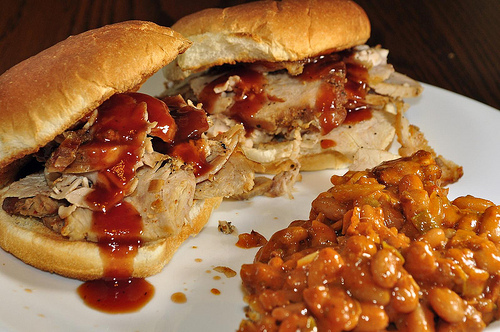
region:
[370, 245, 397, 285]
baked bean piled on white plate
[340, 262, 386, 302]
baked bean piled on white plate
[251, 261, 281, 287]
baked bean piled on white plate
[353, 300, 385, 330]
baked bean piled on white plate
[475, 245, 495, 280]
baked bean piled on white plate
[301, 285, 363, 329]
baked bean piled on white plate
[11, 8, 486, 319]
a white plate of food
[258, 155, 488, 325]
serving of baked beans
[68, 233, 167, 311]
dripping bbq sauce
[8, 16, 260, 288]
bbq beef sandwhich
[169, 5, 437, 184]
bbq pork sandwich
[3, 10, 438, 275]
two sandwiches with toasted buns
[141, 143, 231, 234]
a hunk of meat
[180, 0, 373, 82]
top bun of bun set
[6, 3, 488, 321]
bbq dinner on a white plate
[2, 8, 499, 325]
food on a round white plate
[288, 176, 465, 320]
beans and rice on a plate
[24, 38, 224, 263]
sandwich on a plate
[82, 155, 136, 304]
barbecue sauce on the plate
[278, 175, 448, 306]
beans on a white plate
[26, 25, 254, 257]
half of sandwich on a plate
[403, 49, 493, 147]
white plate on a table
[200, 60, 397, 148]
meat in between the bread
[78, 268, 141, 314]
red sauce on the plate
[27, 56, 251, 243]
sandwich with meat and sauce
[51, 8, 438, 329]
food on a white plate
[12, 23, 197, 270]
this is a sandwich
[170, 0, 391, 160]
this is a sandwich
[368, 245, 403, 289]
this is a grain of bean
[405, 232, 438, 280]
this is a grain of bean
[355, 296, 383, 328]
this is a grain of bean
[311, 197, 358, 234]
this is a grain of bean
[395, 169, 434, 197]
this is a grain of bean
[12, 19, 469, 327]
a meal on a plate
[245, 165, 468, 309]
baked beans on a plate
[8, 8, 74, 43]
wooden table in the back ground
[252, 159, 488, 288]
pile of beans on a plate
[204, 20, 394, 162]
a barbecue sandwich on a plate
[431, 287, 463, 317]
brown bean in sauce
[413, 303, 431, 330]
brown bean in sauce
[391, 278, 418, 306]
brown bean in sauce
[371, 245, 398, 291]
brown bean in sauce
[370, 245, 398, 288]
bean piled on top of bean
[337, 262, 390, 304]
bean piled on top of bean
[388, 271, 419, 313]
bean piled on top of bean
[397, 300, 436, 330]
bean piled on top of bean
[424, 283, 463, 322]
bean piled on top of bean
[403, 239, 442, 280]
bean piled on top of bean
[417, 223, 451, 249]
bean piled on top of bean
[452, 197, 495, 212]
bean piled on top of bean